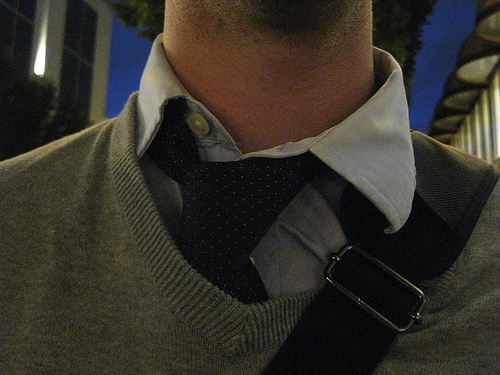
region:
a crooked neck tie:
[150, 117, 316, 301]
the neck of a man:
[164, 41, 373, 148]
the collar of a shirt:
[133, 32, 417, 231]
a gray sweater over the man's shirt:
[2, 92, 499, 372]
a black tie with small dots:
[155, 107, 320, 300]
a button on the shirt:
[187, 113, 210, 138]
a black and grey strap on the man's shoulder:
[263, 133, 495, 373]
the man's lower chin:
[241, 0, 344, 30]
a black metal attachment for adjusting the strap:
[324, 242, 428, 335]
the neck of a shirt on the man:
[132, 32, 417, 234]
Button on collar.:
[188, 113, 210, 140]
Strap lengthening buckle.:
[314, 222, 434, 337]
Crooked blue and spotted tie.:
[141, 103, 333, 309]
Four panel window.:
[54, 3, 98, 127]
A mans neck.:
[161, 1, 389, 170]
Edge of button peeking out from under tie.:
[246, 249, 262, 264]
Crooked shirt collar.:
[96, 11, 433, 238]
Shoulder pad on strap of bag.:
[307, 112, 498, 293]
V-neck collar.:
[81, 86, 327, 356]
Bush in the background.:
[1, 65, 91, 163]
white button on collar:
[180, 109, 215, 144]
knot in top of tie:
[168, 148, 315, 275]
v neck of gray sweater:
[192, 272, 307, 357]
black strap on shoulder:
[317, 164, 482, 353]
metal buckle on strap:
[318, 240, 430, 335]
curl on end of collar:
[365, 183, 420, 245]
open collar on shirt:
[210, 101, 312, 163]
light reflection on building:
[28, 11, 62, 81]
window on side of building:
[55, 2, 109, 112]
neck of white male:
[229, 13, 351, 111]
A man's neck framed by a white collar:
[128, 1, 419, 227]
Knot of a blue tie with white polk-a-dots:
[162, 124, 324, 304]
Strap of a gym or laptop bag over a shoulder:
[274, 132, 497, 372]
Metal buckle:
[320, 240, 434, 332]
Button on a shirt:
[181, 104, 224, 141]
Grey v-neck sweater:
[1, 87, 498, 374]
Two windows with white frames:
[0, 1, 112, 125]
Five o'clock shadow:
[166, 1, 373, 56]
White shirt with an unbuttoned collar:
[133, 26, 426, 284]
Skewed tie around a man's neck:
[142, 88, 337, 300]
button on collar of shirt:
[187, 109, 216, 146]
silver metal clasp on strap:
[321, 235, 433, 339]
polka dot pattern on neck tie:
[184, 165, 261, 227]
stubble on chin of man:
[240, 0, 347, 42]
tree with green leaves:
[375, 0, 432, 53]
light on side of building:
[32, 10, 50, 83]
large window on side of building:
[58, 0, 106, 120]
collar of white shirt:
[315, 79, 428, 224]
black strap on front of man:
[259, 325, 395, 374]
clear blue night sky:
[107, 37, 137, 92]